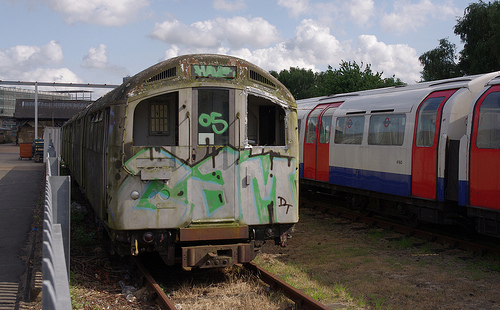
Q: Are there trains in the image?
A: Yes, there is a train.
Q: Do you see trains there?
A: Yes, there is a train.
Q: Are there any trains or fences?
A: Yes, there is a train.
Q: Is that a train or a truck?
A: That is a train.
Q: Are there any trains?
A: Yes, there is a train.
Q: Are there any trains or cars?
A: Yes, there is a train.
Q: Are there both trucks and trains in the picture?
A: No, there is a train but no trucks.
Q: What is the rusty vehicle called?
A: The vehicle is a train.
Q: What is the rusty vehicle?
A: The vehicle is a train.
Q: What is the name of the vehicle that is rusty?
A: The vehicle is a train.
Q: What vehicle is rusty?
A: The vehicle is a train.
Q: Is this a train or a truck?
A: This is a train.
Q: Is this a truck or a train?
A: This is a train.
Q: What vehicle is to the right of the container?
A: The vehicle is a train.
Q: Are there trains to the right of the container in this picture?
A: Yes, there is a train to the right of the container.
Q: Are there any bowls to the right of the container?
A: No, there is a train to the right of the container.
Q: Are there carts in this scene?
A: No, there are no carts.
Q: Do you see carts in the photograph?
A: No, there are no carts.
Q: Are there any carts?
A: No, there are no carts.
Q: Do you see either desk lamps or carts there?
A: No, there are no carts or desk lamps.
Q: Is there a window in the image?
A: Yes, there is a window.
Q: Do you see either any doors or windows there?
A: Yes, there is a window.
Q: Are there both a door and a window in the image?
A: Yes, there are both a window and a door.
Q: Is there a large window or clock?
A: Yes, there is a large window.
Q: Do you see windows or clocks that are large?
A: Yes, the window is large.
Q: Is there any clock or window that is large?
A: Yes, the window is large.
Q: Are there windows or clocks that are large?
A: Yes, the window is large.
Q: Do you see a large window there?
A: Yes, there is a large window.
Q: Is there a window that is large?
A: Yes, there is a window that is large.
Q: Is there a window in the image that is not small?
A: Yes, there is a large window.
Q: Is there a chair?
A: No, there are no chairs.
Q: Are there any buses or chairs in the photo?
A: No, there are no chairs or buses.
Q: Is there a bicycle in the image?
A: No, there are no bicycles.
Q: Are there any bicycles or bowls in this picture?
A: No, there are no bicycles or bowls.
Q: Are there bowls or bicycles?
A: No, there are no bicycles or bowls.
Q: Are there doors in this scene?
A: Yes, there is a door.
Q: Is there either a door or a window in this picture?
A: Yes, there is a door.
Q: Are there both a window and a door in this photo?
A: Yes, there are both a door and a window.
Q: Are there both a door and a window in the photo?
A: Yes, there are both a door and a window.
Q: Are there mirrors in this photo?
A: No, there are no mirrors.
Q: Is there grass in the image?
A: Yes, there is grass.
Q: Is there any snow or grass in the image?
A: Yes, there is grass.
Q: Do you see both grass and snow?
A: No, there is grass but no snow.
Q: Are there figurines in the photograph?
A: No, there are no figurines.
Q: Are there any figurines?
A: No, there are no figurines.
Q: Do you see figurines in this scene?
A: No, there are no figurines.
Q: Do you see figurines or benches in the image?
A: No, there are no figurines or benches.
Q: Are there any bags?
A: No, there are no bags.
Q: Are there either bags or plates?
A: No, there are no bags or plates.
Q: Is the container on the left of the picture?
A: Yes, the container is on the left of the image.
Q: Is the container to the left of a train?
A: Yes, the container is to the left of a train.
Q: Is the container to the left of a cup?
A: No, the container is to the left of a train.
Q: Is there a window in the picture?
A: Yes, there is a window.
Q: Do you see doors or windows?
A: Yes, there is a window.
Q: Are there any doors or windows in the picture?
A: Yes, there is a window.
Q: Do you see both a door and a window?
A: Yes, there are both a window and a door.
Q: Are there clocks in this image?
A: No, there are no clocks.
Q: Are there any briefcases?
A: No, there are no briefcases.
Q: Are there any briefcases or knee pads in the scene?
A: No, there are no briefcases or knee pads.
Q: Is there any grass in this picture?
A: Yes, there is grass.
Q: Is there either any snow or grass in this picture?
A: Yes, there is grass.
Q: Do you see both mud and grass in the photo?
A: No, there is grass but no mud.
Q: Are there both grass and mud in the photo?
A: No, there is grass but no mud.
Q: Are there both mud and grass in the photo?
A: No, there is grass but no mud.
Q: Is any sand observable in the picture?
A: No, there is no sand.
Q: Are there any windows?
A: Yes, there is a window.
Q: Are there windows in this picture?
A: Yes, there is a window.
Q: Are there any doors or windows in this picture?
A: Yes, there is a window.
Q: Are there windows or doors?
A: Yes, there is a window.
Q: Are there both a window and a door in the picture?
A: Yes, there are both a window and a door.